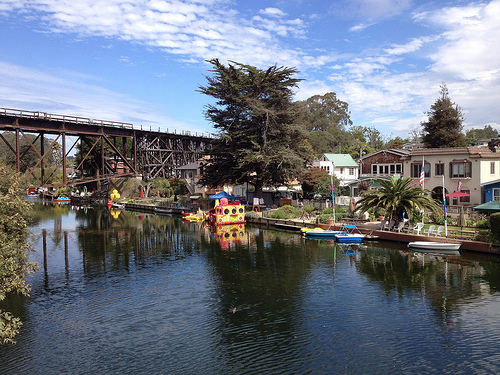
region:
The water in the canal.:
[29, 195, 494, 370]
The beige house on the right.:
[407, 142, 499, 202]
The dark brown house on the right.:
[355, 142, 410, 184]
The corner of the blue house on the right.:
[475, 172, 499, 207]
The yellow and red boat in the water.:
[182, 191, 259, 231]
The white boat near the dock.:
[407, 236, 467, 250]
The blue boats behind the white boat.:
[299, 217, 372, 247]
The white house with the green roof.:
[307, 147, 354, 185]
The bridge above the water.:
[10, 97, 229, 156]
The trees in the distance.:
[2, 126, 80, 184]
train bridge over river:
[2, 97, 250, 202]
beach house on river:
[347, 137, 498, 239]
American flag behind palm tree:
[414, 151, 429, 243]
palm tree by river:
[356, 166, 429, 236]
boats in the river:
[290, 214, 458, 259]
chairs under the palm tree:
[370, 212, 445, 238]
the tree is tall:
[200, 44, 313, 217]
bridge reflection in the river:
[22, 203, 205, 295]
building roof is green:
[313, 145, 363, 184]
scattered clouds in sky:
[5, 0, 497, 127]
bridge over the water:
[0, 100, 239, 216]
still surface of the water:
[15, 200, 497, 372]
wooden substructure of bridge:
[125, 129, 222, 191]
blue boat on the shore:
[330, 225, 375, 250]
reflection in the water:
[15, 209, 95, 312]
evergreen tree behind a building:
[412, 75, 470, 163]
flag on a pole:
[413, 145, 433, 227]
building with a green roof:
[302, 140, 362, 199]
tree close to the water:
[187, 53, 329, 227]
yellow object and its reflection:
[202, 201, 247, 256]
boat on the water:
[328, 222, 373, 244]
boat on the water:
[402, 230, 467, 256]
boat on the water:
[298, 218, 346, 241]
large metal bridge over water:
[0, 100, 238, 213]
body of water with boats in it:
[5, 193, 499, 374]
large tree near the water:
[191, 55, 308, 220]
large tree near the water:
[412, 80, 468, 155]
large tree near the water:
[351, 172, 438, 249]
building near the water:
[398, 135, 498, 217]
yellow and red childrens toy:
[207, 195, 247, 231]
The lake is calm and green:
[68, 244, 435, 373]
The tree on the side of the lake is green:
[1, 131, 44, 370]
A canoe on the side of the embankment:
[398, 236, 471, 260]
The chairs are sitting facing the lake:
[369, 215, 455, 240]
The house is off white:
[396, 138, 490, 215]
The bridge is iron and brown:
[6, 93, 201, 175]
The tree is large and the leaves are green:
[188, 53, 335, 204]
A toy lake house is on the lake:
[176, 190, 248, 233]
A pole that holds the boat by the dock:
[313, 160, 346, 228]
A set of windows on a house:
[343, 128, 410, 178]